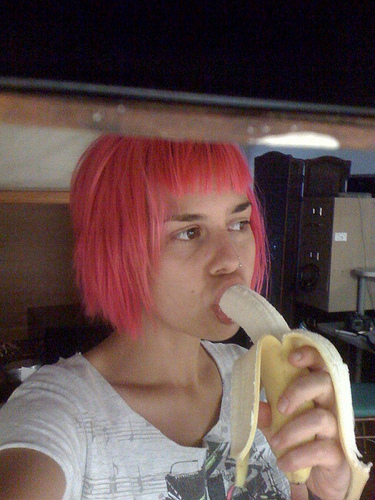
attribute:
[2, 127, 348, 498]
lady — light skinned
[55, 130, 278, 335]
hair — pink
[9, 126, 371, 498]
person — inside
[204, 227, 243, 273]
nose — stud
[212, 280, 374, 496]
banana — peeled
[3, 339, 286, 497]
shirt — white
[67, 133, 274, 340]
hair — pink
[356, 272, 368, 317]
polte — silver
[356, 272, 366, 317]
pole — silver